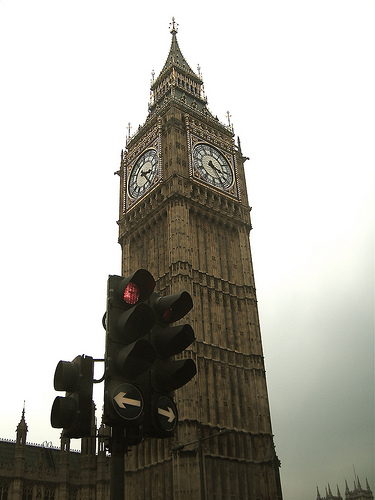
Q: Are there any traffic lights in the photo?
A: Yes, there is a traffic light.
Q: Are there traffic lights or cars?
A: Yes, there is a traffic light.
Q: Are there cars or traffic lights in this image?
A: Yes, there is a traffic light.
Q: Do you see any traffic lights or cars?
A: Yes, there is a traffic light.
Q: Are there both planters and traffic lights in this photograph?
A: No, there is a traffic light but no planters.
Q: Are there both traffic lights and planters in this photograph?
A: No, there is a traffic light but no planters.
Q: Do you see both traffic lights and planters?
A: No, there is a traffic light but no planters.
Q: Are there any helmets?
A: No, there are no helmets.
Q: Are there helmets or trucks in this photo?
A: No, there are no helmets or trucks.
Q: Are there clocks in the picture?
A: Yes, there is a clock.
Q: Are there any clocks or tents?
A: Yes, there is a clock.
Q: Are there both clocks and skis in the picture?
A: No, there is a clock but no skis.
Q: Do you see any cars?
A: No, there are no cars.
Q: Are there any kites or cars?
A: No, there are no cars or kites.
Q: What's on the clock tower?
A: The clock is on the clock tower.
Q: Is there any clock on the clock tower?
A: Yes, there is a clock on the clock tower.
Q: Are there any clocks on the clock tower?
A: Yes, there is a clock on the clock tower.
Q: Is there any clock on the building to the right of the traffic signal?
A: Yes, there is a clock on the clock tower.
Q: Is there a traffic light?
A: Yes, there is a traffic light.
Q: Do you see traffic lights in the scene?
A: Yes, there is a traffic light.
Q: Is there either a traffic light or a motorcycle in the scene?
A: Yes, there is a traffic light.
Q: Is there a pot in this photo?
A: No, there are no pots.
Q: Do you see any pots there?
A: No, there are no pots.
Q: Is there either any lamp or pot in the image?
A: No, there are no pots or lamps.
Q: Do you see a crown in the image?
A: No, there are no crowns.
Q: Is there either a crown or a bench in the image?
A: No, there are no crowns or benches.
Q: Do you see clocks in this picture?
A: Yes, there is a clock.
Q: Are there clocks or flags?
A: Yes, there is a clock.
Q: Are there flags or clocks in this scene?
A: Yes, there is a clock.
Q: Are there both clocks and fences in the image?
A: No, there is a clock but no fences.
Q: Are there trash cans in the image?
A: No, there are no trash cans.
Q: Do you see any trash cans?
A: No, there are no trash cans.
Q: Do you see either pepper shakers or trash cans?
A: No, there are no trash cans or pepper shakers.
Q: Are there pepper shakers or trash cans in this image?
A: No, there are no trash cans or pepper shakers.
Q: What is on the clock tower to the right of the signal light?
A: The clock is on the clock tower.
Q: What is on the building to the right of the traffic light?
A: The clock is on the clock tower.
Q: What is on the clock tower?
A: The clock is on the clock tower.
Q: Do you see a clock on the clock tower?
A: Yes, there is a clock on the clock tower.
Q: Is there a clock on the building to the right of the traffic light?
A: Yes, there is a clock on the clock tower.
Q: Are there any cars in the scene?
A: No, there are no cars.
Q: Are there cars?
A: No, there are no cars.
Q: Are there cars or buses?
A: No, there are no cars or buses.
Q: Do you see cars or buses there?
A: No, there are no cars or buses.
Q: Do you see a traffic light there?
A: Yes, there is a traffic light.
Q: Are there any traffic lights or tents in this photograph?
A: Yes, there is a traffic light.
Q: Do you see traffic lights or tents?
A: Yes, there is a traffic light.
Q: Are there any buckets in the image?
A: No, there are no buckets.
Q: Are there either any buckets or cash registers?
A: No, there are no buckets or cash registers.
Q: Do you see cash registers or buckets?
A: No, there are no buckets or cash registers.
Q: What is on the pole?
A: The traffic light is on the pole.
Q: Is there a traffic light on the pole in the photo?
A: Yes, there is a traffic light on the pole.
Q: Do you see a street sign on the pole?
A: No, there is a traffic light on the pole.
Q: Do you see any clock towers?
A: Yes, there is a clock tower.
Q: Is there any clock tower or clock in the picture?
A: Yes, there is a clock tower.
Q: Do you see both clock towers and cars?
A: No, there is a clock tower but no cars.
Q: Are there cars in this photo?
A: No, there are no cars.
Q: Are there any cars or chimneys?
A: No, there are no cars or chimneys.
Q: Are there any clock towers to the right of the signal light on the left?
A: Yes, there is a clock tower to the right of the traffic signal.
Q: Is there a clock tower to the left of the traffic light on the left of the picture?
A: No, the clock tower is to the right of the traffic signal.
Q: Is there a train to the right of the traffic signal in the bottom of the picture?
A: No, there is a clock tower to the right of the traffic light.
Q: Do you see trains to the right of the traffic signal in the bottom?
A: No, there is a clock tower to the right of the traffic light.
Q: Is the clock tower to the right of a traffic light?
A: Yes, the clock tower is to the right of a traffic light.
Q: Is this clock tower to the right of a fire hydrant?
A: No, the clock tower is to the right of a traffic light.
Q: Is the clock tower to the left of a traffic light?
A: No, the clock tower is to the right of a traffic light.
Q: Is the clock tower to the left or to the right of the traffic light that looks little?
A: The clock tower is to the right of the traffic light.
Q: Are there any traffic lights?
A: Yes, there is a traffic light.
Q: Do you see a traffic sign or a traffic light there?
A: Yes, there is a traffic light.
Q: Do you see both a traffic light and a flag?
A: No, there is a traffic light but no flags.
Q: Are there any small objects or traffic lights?
A: Yes, there is a small traffic light.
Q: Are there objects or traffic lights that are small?
A: Yes, the traffic light is small.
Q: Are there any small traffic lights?
A: Yes, there is a small traffic light.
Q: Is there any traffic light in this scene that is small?
A: Yes, there is a traffic light that is small.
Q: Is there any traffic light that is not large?
A: Yes, there is a small traffic light.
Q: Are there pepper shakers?
A: No, there are no pepper shakers.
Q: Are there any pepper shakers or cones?
A: No, there are no pepper shakers or cones.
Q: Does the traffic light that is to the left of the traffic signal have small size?
A: Yes, the traffic light is small.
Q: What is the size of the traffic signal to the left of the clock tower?
A: The traffic signal is small.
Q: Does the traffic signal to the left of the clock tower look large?
A: No, the traffic light is small.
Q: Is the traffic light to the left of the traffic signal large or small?
A: The traffic light is small.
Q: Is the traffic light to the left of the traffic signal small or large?
A: The traffic light is small.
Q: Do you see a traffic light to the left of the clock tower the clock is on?
A: Yes, there is a traffic light to the left of the clock tower.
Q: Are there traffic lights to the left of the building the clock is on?
A: Yes, there is a traffic light to the left of the clock tower.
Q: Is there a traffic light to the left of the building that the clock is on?
A: Yes, there is a traffic light to the left of the clock tower.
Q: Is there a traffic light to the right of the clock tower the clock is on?
A: No, the traffic light is to the left of the clock tower.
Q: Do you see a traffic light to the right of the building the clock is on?
A: No, the traffic light is to the left of the clock tower.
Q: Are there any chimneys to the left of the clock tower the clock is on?
A: No, there is a traffic light to the left of the clock tower.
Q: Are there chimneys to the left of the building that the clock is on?
A: No, there is a traffic light to the left of the clock tower.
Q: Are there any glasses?
A: No, there are no glasses.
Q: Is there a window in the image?
A: Yes, there are windows.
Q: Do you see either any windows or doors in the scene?
A: Yes, there are windows.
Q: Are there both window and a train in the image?
A: No, there are windows but no trains.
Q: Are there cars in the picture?
A: No, there are no cars.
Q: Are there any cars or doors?
A: No, there are no cars or doors.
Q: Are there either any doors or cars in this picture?
A: No, there are no cars or doors.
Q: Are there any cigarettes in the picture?
A: No, there are no cigarettes.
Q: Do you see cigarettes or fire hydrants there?
A: No, there are no cigarettes or fire hydrants.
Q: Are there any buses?
A: No, there are no buses.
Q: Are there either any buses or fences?
A: No, there are no buses or fences.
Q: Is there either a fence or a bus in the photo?
A: No, there are no buses or fences.